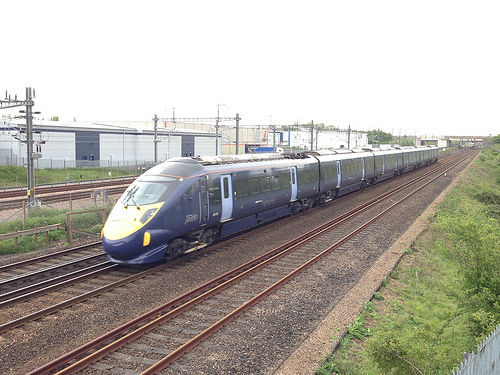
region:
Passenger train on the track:
[98, 141, 442, 273]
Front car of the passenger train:
[97, 152, 321, 269]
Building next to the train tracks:
[3, 124, 220, 166]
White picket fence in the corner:
[455, 327, 497, 373]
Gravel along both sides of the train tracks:
[1, 144, 480, 371]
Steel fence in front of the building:
[1, 154, 150, 172]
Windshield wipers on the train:
[121, 181, 140, 215]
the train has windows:
[176, 152, 353, 227]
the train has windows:
[76, 142, 338, 269]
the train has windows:
[81, 135, 358, 275]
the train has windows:
[80, 127, 370, 299]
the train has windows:
[87, 150, 382, 291]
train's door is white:
[210, 170, 242, 231]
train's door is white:
[276, 156, 303, 211]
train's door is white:
[328, 160, 348, 194]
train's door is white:
[207, 163, 247, 222]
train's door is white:
[204, 168, 245, 241]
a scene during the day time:
[10, 65, 498, 369]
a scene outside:
[10, 72, 498, 373]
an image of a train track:
[9, 58, 496, 373]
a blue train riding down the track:
[92, 116, 460, 284]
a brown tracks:
[69, 211, 344, 373]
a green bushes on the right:
[369, 135, 496, 373]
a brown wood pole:
[5, 81, 57, 196]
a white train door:
[206, 162, 257, 247]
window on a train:
[122, 178, 169, 208]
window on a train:
[207, 176, 220, 201]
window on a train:
[222, 177, 231, 197]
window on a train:
[235, 178, 248, 198]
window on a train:
[248, 178, 258, 193]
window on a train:
[260, 176, 273, 190]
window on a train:
[270, 174, 280, 191]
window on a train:
[290, 167, 297, 186]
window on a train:
[303, 166, 310, 183]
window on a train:
[333, 160, 341, 176]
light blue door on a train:
[215, 170, 237, 223]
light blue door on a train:
[284, 165, 301, 203]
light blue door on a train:
[332, 158, 343, 190]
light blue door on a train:
[357, 154, 368, 182]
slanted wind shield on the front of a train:
[116, 170, 180, 212]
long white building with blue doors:
[0, 118, 223, 173]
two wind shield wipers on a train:
[120, 179, 146, 213]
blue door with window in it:
[218, 173, 235, 229]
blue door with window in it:
[285, 165, 300, 204]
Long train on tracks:
[95, 145, 435, 267]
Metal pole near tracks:
[20, 84, 47, 206]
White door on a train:
[217, 173, 236, 222]